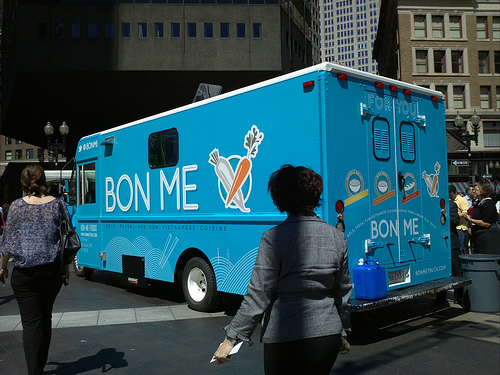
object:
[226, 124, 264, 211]
carrot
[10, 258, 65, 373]
pants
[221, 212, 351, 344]
shirt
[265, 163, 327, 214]
hair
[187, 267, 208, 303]
rim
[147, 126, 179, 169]
window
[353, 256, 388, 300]
container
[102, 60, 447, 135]
roof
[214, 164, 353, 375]
woman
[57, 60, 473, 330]
truck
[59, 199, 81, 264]
purse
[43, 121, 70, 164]
lamp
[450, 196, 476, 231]
shirt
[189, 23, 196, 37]
window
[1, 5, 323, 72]
building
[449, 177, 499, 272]
people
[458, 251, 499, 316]
bin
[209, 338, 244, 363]
envelop